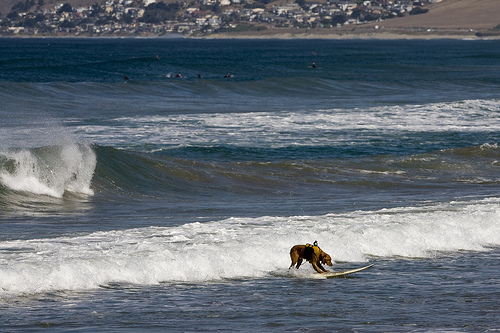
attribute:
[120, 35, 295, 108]
people — in the background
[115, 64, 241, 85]
people — in the distance, swimming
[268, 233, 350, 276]
dog — brown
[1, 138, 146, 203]
waves — white, blue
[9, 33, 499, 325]
waves — white, blue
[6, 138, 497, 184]
wave — white, blue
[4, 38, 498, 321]
ocean — white, blue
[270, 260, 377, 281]
surfoboard — white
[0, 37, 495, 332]
water — calm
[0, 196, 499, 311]
foam — white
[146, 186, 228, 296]
waves — white, blue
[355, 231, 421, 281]
waves — blue, white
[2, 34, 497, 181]
waves — white, blue